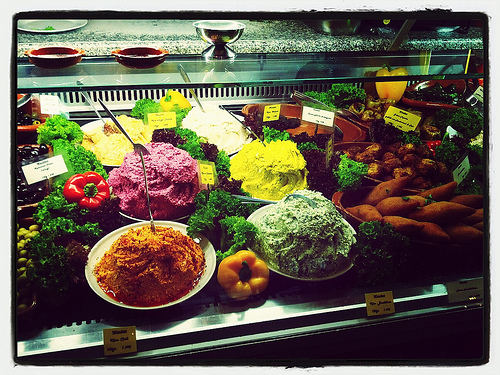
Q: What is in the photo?
A: Vegetables.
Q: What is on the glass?
A: Price tag.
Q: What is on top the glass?
A: Bowls.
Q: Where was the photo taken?
A: Store.